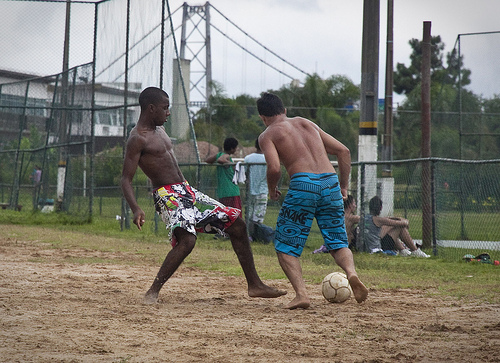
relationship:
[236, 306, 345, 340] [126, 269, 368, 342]
dirt on field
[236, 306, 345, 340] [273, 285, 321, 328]
dirt in footprints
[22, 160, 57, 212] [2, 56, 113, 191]
girl sitting on fence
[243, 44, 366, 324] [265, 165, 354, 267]
man in blue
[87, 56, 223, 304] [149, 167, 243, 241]
man wearing shorts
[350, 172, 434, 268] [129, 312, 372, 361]
person on ground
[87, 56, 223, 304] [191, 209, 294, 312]
man lifting foot